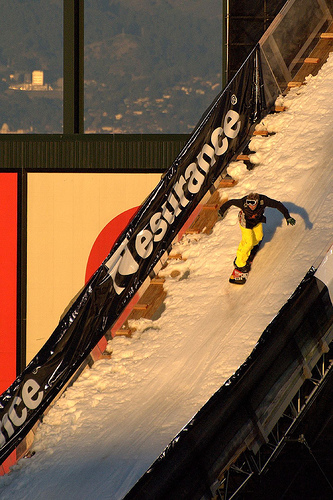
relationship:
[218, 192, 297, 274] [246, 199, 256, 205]
man wearing goggles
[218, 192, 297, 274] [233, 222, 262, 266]
man wearing pants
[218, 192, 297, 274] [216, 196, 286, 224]
man wearing jacket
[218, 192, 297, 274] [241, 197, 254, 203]
man wearing goggles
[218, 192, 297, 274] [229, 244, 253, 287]
man on snowboard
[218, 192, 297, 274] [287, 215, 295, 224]
man wearing glove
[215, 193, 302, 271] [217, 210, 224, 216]
man wearing glove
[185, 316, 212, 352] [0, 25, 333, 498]
snow on ramp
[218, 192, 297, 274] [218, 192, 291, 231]
man wearing jacket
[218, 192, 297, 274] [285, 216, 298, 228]
man wearing gloves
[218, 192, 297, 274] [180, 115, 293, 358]
man flies down ramp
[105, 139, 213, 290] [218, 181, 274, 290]
banner next to snowboarder